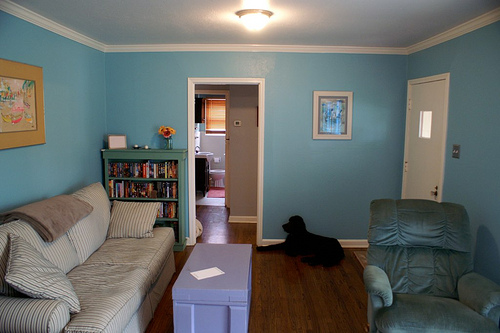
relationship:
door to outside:
[395, 70, 453, 201] [144, 56, 396, 333]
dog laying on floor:
[253, 213, 347, 270] [121, 236, 371, 331]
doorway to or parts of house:
[191, 78, 264, 240] [189, 60, 496, 253]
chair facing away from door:
[361, 197, 497, 332] [216, 121, 278, 288]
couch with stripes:
[0, 183, 177, 331] [0, 184, 178, 331]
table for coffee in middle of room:
[170, 241, 255, 332] [2, 3, 499, 328]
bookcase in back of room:
[100, 146, 189, 253] [148, 83, 199, 220]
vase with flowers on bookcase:
[163, 135, 174, 146] [105, 162, 173, 212]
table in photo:
[165, 237, 260, 324] [207, 235, 264, 321]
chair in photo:
[361, 197, 497, 332] [262, 268, 407, 317]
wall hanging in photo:
[102, 44, 407, 251] [93, 53, 423, 220]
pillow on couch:
[35, 228, 70, 290] [15, 164, 206, 322]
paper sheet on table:
[192, 266, 224, 279] [175, 245, 247, 329]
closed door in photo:
[332, 121, 452, 215] [122, 151, 470, 333]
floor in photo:
[144, 218, 370, 333] [65, 164, 415, 333]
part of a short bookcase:
[177, 130, 192, 256] [100, 146, 189, 253]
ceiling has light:
[107, 5, 173, 40] [232, 8, 271, 32]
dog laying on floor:
[253, 213, 347, 270] [263, 276, 350, 324]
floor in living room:
[263, 276, 350, 324] [17, 37, 489, 329]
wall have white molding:
[0, 0, 499, 289] [234, 35, 301, 51]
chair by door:
[361, 197, 497, 332] [401, 78, 448, 203]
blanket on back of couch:
[3, 193, 94, 245] [0, 183, 177, 331]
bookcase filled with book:
[100, 146, 189, 253] [112, 159, 119, 177]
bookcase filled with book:
[100, 146, 189, 253] [151, 156, 157, 174]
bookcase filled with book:
[100, 146, 189, 253] [162, 179, 169, 199]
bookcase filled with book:
[100, 146, 189, 253] [130, 162, 139, 180]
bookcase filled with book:
[100, 146, 189, 253] [153, 180, 161, 200]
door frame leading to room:
[174, 65, 274, 250] [192, 90, 252, 235]